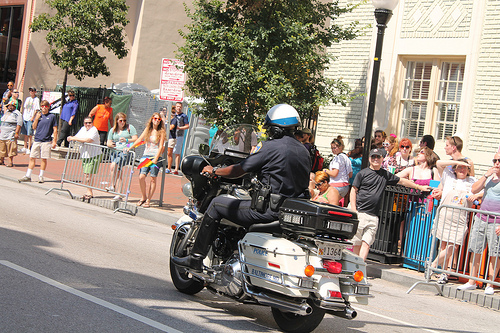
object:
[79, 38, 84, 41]
leaves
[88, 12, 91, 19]
leaves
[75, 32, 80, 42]
leaves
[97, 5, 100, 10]
leaves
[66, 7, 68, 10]
leaves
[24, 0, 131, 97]
tree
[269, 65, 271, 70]
leaves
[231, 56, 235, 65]
leaves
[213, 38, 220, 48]
leaves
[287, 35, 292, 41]
leaves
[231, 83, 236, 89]
leaves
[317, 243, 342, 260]
plate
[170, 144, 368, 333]
bike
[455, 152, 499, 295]
person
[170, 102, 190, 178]
person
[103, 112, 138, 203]
people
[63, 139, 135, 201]
gate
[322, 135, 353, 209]
girl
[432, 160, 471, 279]
lady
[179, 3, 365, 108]
leaves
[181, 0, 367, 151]
tree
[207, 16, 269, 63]
leaves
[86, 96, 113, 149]
man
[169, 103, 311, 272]
cop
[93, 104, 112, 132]
shirt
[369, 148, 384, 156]
cap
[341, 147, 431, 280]
man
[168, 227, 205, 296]
tire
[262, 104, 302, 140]
helmet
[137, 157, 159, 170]
flag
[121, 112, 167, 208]
girl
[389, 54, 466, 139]
windows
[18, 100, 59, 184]
standing man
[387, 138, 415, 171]
person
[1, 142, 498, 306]
sidewalk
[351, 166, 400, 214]
shirt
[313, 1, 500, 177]
building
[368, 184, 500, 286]
rail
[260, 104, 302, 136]
head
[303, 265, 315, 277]
lights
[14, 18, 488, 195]
sun